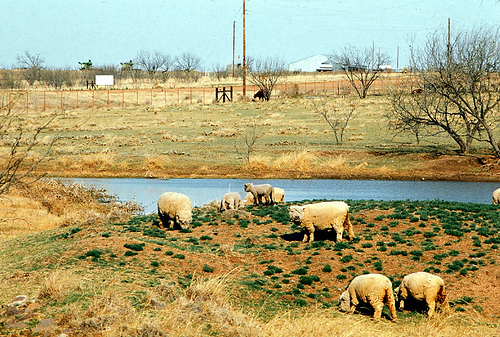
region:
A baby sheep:
[241, 178, 276, 205]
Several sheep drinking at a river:
[217, 181, 282, 214]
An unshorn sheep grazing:
[150, 187, 197, 244]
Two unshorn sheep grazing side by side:
[333, 266, 457, 326]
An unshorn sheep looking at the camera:
[281, 197, 358, 246]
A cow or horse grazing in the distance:
[243, 82, 275, 107]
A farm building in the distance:
[268, 47, 361, 79]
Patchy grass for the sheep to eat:
[361, 203, 483, 260]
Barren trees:
[393, 29, 495, 160]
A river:
[68, 172, 498, 206]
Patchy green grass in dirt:
[371, 200, 458, 230]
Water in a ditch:
[341, 175, 466, 205]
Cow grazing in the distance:
[249, 85, 281, 104]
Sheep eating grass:
[153, 192, 208, 234]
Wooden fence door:
[212, 81, 234, 103]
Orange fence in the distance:
[98, 87, 215, 106]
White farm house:
[274, 52, 392, 74]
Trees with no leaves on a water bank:
[408, 60, 498, 150]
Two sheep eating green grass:
[336, 262, 458, 319]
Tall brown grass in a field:
[163, 270, 287, 335]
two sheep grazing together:
[342, 253, 455, 323]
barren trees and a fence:
[313, 36, 485, 162]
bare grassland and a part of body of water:
[105, 113, 255, 185]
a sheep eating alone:
[157, 180, 209, 247]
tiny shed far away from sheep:
[36, 51, 156, 111]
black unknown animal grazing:
[251, 48, 271, 111]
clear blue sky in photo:
[33, 24, 223, 69]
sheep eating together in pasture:
[157, 168, 450, 323]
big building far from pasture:
[296, 43, 393, 117]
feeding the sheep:
[41, 96, 463, 325]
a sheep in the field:
[138, 183, 200, 248]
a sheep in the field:
[335, 251, 405, 330]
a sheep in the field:
[402, 250, 445, 314]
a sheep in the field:
[206, 179, 242, 220]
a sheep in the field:
[247, 177, 276, 210]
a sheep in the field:
[287, 187, 354, 245]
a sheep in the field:
[483, 181, 498, 213]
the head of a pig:
[171, 210, 201, 236]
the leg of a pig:
[330, 219, 350, 244]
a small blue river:
[29, 167, 497, 242]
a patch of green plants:
[259, 259, 287, 279]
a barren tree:
[371, 20, 498, 173]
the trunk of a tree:
[443, 119, 482, 152]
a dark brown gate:
[211, 81, 236, 105]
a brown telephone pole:
[237, 0, 254, 97]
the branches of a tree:
[377, 20, 497, 140]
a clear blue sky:
[0, 0, 499, 74]